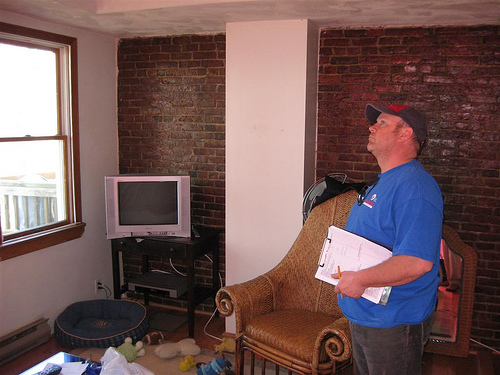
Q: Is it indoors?
A: Yes, it is indoors.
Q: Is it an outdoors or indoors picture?
A: It is indoors.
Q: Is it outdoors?
A: No, it is indoors.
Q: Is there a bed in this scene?
A: Yes, there is a bed.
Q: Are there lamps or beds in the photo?
A: Yes, there is a bed.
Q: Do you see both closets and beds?
A: No, there is a bed but no closets.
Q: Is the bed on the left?
A: Yes, the bed is on the left of the image.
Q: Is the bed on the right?
A: No, the bed is on the left of the image.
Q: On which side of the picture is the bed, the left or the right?
A: The bed is on the left of the image.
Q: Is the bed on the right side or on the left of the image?
A: The bed is on the left of the image.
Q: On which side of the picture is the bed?
A: The bed is on the left of the image.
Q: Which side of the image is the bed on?
A: The bed is on the left of the image.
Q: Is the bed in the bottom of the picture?
A: Yes, the bed is in the bottom of the image.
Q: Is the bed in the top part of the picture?
A: No, the bed is in the bottom of the image.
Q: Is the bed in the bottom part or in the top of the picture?
A: The bed is in the bottom of the image.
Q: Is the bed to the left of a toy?
A: Yes, the bed is to the left of a toy.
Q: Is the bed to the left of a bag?
A: No, the bed is to the left of a toy.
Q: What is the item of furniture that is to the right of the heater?
A: The piece of furniture is a bed.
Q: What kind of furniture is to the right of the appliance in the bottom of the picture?
A: The piece of furniture is a bed.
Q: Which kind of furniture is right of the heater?
A: The piece of furniture is a bed.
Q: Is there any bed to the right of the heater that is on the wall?
A: Yes, there is a bed to the right of the heater.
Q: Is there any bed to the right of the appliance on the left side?
A: Yes, there is a bed to the right of the heater.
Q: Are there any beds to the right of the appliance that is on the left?
A: Yes, there is a bed to the right of the heater.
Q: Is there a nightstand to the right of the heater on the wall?
A: No, there is a bed to the right of the heater.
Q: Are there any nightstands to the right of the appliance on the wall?
A: No, there is a bed to the right of the heater.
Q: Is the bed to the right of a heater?
A: Yes, the bed is to the right of a heater.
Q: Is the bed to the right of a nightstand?
A: No, the bed is to the right of a heater.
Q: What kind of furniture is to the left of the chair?
A: The piece of furniture is a bed.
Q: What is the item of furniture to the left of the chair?
A: The piece of furniture is a bed.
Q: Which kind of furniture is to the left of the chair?
A: The piece of furniture is a bed.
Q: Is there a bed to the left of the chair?
A: Yes, there is a bed to the left of the chair.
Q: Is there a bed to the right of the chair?
A: No, the bed is to the left of the chair.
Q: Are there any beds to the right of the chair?
A: No, the bed is to the left of the chair.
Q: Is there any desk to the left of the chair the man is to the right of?
A: No, there is a bed to the left of the chair.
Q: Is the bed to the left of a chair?
A: Yes, the bed is to the left of a chair.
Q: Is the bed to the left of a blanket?
A: No, the bed is to the left of a chair.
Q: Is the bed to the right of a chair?
A: No, the bed is to the left of a chair.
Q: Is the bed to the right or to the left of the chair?
A: The bed is to the left of the chair.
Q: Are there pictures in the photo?
A: No, there are no pictures.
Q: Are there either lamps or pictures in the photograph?
A: No, there are no pictures or lamps.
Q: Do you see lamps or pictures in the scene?
A: No, there are no pictures or lamps.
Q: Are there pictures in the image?
A: No, there are no pictures.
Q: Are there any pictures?
A: No, there are no pictures.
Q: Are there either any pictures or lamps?
A: No, there are no pictures or lamps.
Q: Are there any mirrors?
A: Yes, there is a mirror.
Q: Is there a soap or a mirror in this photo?
A: Yes, there is a mirror.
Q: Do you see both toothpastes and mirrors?
A: No, there is a mirror but no toothpastes.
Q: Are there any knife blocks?
A: No, there are no knife blocks.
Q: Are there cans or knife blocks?
A: No, there are no knife blocks or cans.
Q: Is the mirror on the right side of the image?
A: Yes, the mirror is on the right of the image.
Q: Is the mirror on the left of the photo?
A: No, the mirror is on the right of the image.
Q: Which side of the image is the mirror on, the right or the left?
A: The mirror is on the right of the image.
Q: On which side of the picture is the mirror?
A: The mirror is on the right of the image.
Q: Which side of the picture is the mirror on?
A: The mirror is on the right of the image.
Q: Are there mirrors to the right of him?
A: Yes, there is a mirror to the right of the man.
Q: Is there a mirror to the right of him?
A: Yes, there is a mirror to the right of the man.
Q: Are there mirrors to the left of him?
A: No, the mirror is to the right of the man.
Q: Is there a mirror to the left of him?
A: No, the mirror is to the right of the man.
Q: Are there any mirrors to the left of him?
A: No, the mirror is to the right of the man.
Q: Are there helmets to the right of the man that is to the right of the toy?
A: No, there is a mirror to the right of the man.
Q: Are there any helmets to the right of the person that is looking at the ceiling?
A: No, there is a mirror to the right of the man.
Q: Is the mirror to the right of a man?
A: Yes, the mirror is to the right of a man.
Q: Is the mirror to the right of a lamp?
A: No, the mirror is to the right of a man.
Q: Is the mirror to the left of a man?
A: No, the mirror is to the right of a man.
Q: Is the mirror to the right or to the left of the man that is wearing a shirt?
A: The mirror is to the right of the man.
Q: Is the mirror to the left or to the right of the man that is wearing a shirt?
A: The mirror is to the right of the man.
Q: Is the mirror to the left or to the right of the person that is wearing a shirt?
A: The mirror is to the right of the man.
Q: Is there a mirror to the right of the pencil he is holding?
A: Yes, there is a mirror to the right of the pencil.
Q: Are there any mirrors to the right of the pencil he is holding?
A: Yes, there is a mirror to the right of the pencil.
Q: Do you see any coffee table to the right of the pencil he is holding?
A: No, there is a mirror to the right of the pencil.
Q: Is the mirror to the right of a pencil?
A: Yes, the mirror is to the right of a pencil.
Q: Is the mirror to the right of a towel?
A: No, the mirror is to the right of a pencil.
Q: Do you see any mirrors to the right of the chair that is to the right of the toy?
A: Yes, there is a mirror to the right of the chair.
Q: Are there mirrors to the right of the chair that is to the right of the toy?
A: Yes, there is a mirror to the right of the chair.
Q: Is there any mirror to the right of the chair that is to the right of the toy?
A: Yes, there is a mirror to the right of the chair.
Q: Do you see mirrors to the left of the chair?
A: No, the mirror is to the right of the chair.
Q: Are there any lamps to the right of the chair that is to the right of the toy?
A: No, there is a mirror to the right of the chair.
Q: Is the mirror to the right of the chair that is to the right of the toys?
A: Yes, the mirror is to the right of the chair.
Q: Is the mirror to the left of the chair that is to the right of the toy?
A: No, the mirror is to the right of the chair.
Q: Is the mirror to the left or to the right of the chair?
A: The mirror is to the right of the chair.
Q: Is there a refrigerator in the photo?
A: No, there are no refrigerators.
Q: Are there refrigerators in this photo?
A: No, there are no refrigerators.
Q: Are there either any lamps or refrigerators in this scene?
A: No, there are no refrigerators or lamps.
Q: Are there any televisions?
A: Yes, there is a television.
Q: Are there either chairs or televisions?
A: Yes, there is a television.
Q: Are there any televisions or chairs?
A: Yes, there is a television.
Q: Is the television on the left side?
A: Yes, the television is on the left of the image.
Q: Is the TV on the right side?
A: No, the TV is on the left of the image.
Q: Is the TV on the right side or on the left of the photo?
A: The TV is on the left of the image.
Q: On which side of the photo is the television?
A: The television is on the left of the image.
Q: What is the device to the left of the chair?
A: The device is a television.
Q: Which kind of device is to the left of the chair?
A: The device is a television.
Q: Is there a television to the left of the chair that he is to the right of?
A: Yes, there is a television to the left of the chair.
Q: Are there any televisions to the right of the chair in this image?
A: No, the television is to the left of the chair.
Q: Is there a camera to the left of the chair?
A: No, there is a television to the left of the chair.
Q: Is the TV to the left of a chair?
A: Yes, the TV is to the left of a chair.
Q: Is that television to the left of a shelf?
A: No, the television is to the left of a chair.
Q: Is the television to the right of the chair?
A: No, the television is to the left of the chair.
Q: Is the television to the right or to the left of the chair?
A: The television is to the left of the chair.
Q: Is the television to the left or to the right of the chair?
A: The television is to the left of the chair.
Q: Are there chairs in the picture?
A: Yes, there is a chair.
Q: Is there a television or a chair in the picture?
A: Yes, there is a chair.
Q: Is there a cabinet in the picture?
A: No, there are no cabinets.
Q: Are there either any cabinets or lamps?
A: No, there are no cabinets or lamps.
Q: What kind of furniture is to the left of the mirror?
A: The piece of furniture is a chair.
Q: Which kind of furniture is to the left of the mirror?
A: The piece of furniture is a chair.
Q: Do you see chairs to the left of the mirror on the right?
A: Yes, there is a chair to the left of the mirror.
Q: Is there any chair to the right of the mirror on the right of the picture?
A: No, the chair is to the left of the mirror.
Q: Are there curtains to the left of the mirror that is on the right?
A: No, there is a chair to the left of the mirror.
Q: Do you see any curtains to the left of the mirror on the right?
A: No, there is a chair to the left of the mirror.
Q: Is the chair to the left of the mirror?
A: Yes, the chair is to the left of the mirror.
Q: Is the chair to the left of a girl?
A: No, the chair is to the left of the mirror.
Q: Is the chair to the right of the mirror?
A: No, the chair is to the left of the mirror.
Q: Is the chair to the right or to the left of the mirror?
A: The chair is to the left of the mirror.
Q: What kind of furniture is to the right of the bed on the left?
A: The piece of furniture is a chair.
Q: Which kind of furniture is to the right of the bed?
A: The piece of furniture is a chair.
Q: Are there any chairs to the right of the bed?
A: Yes, there is a chair to the right of the bed.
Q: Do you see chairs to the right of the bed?
A: Yes, there is a chair to the right of the bed.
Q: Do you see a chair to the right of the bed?
A: Yes, there is a chair to the right of the bed.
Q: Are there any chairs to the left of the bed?
A: No, the chair is to the right of the bed.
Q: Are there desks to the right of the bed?
A: No, there is a chair to the right of the bed.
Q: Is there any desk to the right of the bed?
A: No, there is a chair to the right of the bed.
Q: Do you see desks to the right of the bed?
A: No, there is a chair to the right of the bed.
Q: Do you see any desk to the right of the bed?
A: No, there is a chair to the right of the bed.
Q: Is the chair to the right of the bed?
A: Yes, the chair is to the right of the bed.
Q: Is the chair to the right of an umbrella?
A: No, the chair is to the right of the bed.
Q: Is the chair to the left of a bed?
A: No, the chair is to the right of a bed.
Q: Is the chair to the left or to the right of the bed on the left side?
A: The chair is to the right of the bed.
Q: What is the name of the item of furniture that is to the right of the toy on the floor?
A: The piece of furniture is a chair.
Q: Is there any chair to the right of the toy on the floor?
A: Yes, there is a chair to the right of the toy.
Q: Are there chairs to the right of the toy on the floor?
A: Yes, there is a chair to the right of the toy.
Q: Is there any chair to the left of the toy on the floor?
A: No, the chair is to the right of the toy.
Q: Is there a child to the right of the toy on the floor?
A: No, there is a chair to the right of the toy.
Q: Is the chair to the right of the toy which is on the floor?
A: Yes, the chair is to the right of the toy.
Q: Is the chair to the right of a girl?
A: No, the chair is to the right of the toy.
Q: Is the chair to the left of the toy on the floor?
A: No, the chair is to the right of the toy.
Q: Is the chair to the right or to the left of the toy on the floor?
A: The chair is to the right of the toy.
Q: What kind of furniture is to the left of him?
A: The piece of furniture is a chair.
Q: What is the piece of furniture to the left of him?
A: The piece of furniture is a chair.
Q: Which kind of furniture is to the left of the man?
A: The piece of furniture is a chair.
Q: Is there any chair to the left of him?
A: Yes, there is a chair to the left of the man.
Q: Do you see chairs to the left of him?
A: Yes, there is a chair to the left of the man.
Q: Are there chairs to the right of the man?
A: No, the chair is to the left of the man.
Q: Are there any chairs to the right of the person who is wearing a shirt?
A: No, the chair is to the left of the man.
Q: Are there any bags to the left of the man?
A: No, there is a chair to the left of the man.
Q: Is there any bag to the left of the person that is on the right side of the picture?
A: No, there is a chair to the left of the man.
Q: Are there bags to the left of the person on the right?
A: No, there is a chair to the left of the man.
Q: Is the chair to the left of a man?
A: Yes, the chair is to the left of a man.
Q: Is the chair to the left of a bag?
A: No, the chair is to the left of a man.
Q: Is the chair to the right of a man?
A: No, the chair is to the left of a man.